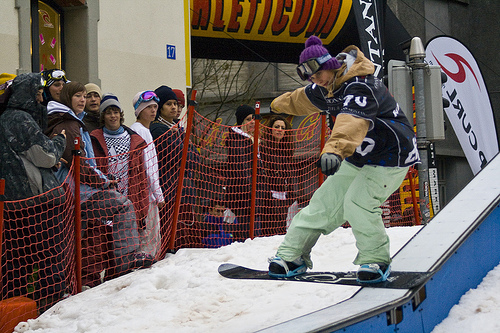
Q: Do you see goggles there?
A: Yes, there are goggles.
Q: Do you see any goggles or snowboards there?
A: Yes, there are goggles.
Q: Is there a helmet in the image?
A: No, there are no helmets.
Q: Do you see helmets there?
A: No, there are no helmets.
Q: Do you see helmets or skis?
A: No, there are no helmets or skis.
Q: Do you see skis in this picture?
A: No, there are no skis.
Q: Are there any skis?
A: No, there are no skis.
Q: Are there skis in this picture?
A: No, there are no skis.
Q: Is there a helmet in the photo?
A: No, there are no helmets.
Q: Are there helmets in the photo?
A: No, there are no helmets.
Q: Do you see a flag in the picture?
A: Yes, there is a flag.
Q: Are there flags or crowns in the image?
A: Yes, there is a flag.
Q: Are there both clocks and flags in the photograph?
A: No, there is a flag but no clocks.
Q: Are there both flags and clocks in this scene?
A: No, there is a flag but no clocks.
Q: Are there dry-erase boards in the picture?
A: No, there are no dry-erase boards.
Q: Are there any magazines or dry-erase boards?
A: No, there are no dry-erase boards or magazines.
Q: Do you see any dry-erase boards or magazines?
A: No, there are no dry-erase boards or magazines.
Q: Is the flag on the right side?
A: Yes, the flag is on the right of the image.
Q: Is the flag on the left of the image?
A: No, the flag is on the right of the image.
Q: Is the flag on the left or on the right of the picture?
A: The flag is on the right of the image.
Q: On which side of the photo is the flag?
A: The flag is on the right of the image.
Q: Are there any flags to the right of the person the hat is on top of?
A: Yes, there is a flag to the right of the person.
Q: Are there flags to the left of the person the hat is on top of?
A: No, the flag is to the right of the person.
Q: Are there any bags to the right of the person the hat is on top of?
A: No, there is a flag to the right of the person.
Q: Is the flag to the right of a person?
A: Yes, the flag is to the right of a person.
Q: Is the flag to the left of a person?
A: No, the flag is to the right of a person.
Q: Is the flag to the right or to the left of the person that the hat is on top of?
A: The flag is to the right of the person.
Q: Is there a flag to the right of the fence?
A: Yes, there is a flag to the right of the fence.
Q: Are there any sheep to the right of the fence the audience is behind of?
A: No, there is a flag to the right of the fence.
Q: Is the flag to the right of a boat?
A: No, the flag is to the right of the fence.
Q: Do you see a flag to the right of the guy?
A: Yes, there is a flag to the right of the guy.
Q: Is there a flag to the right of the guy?
A: Yes, there is a flag to the right of the guy.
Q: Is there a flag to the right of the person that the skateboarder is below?
A: Yes, there is a flag to the right of the guy.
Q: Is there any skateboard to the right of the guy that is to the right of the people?
A: No, there is a flag to the right of the guy.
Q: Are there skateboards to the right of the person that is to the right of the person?
A: No, there is a flag to the right of the guy.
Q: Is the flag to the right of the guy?
A: Yes, the flag is to the right of the guy.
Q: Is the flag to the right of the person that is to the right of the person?
A: Yes, the flag is to the right of the guy.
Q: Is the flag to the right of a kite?
A: No, the flag is to the right of the guy.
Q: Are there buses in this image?
A: No, there are no buses.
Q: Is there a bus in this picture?
A: No, there are no buses.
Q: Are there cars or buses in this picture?
A: No, there are no buses or cars.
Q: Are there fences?
A: Yes, there is a fence.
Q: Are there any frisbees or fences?
A: Yes, there is a fence.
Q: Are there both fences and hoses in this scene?
A: No, there is a fence but no hoses.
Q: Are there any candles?
A: No, there are no candles.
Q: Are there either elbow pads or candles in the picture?
A: No, there are no candles or elbow pads.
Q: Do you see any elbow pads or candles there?
A: No, there are no candles or elbow pads.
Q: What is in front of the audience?
A: The fence is in front of the audience.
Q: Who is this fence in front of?
A: The fence is in front of the audience.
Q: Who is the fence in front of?
A: The fence is in front of the audience.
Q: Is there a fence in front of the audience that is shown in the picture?
A: Yes, there is a fence in front of the audience.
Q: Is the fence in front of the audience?
A: Yes, the fence is in front of the audience.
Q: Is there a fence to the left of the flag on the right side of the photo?
A: Yes, there is a fence to the left of the flag.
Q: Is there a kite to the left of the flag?
A: No, there is a fence to the left of the flag.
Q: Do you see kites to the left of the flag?
A: No, there is a fence to the left of the flag.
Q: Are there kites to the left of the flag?
A: No, there is a fence to the left of the flag.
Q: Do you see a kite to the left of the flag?
A: No, there is a fence to the left of the flag.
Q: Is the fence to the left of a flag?
A: Yes, the fence is to the left of a flag.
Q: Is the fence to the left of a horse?
A: No, the fence is to the left of a flag.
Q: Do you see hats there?
A: Yes, there is a hat.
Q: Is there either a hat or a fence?
A: Yes, there is a hat.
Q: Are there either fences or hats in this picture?
A: Yes, there is a hat.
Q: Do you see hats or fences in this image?
A: Yes, there is a hat.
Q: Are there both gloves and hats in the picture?
A: Yes, there are both a hat and gloves.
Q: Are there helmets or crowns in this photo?
A: No, there are no helmets or crowns.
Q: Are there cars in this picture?
A: No, there are no cars.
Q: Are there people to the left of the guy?
A: Yes, there is a person to the left of the guy.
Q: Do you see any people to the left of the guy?
A: Yes, there is a person to the left of the guy.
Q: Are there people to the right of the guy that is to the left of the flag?
A: No, the person is to the left of the guy.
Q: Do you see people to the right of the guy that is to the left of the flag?
A: No, the person is to the left of the guy.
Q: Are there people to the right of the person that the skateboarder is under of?
A: No, the person is to the left of the guy.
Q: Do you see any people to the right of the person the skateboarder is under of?
A: No, the person is to the left of the guy.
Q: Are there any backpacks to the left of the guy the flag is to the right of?
A: No, there is a person to the left of the guy.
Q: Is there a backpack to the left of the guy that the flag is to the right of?
A: No, there is a person to the left of the guy.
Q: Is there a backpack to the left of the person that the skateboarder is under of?
A: No, there is a person to the left of the guy.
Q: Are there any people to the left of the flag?
A: Yes, there is a person to the left of the flag.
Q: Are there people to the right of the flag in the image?
A: No, the person is to the left of the flag.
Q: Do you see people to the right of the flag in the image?
A: No, the person is to the left of the flag.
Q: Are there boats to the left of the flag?
A: No, there is a person to the left of the flag.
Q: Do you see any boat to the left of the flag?
A: No, there is a person to the left of the flag.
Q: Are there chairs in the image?
A: No, there are no chairs.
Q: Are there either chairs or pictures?
A: No, there are no chairs or pictures.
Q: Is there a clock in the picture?
A: No, there are no clocks.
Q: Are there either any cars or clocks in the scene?
A: No, there are no clocks or cars.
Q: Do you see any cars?
A: No, there are no cars.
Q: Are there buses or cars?
A: No, there are no cars or buses.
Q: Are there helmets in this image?
A: No, there are no helmets.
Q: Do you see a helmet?
A: No, there are no helmets.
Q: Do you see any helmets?
A: No, there are no helmets.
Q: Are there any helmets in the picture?
A: No, there are no helmets.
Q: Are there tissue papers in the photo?
A: No, there are no tissue papers.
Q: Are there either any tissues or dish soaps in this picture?
A: No, there are no tissues or dish soaps.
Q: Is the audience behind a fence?
A: Yes, the audience is behind a fence.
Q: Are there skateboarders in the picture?
A: Yes, there is a skateboarder.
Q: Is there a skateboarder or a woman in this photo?
A: Yes, there is a skateboarder.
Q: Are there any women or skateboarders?
A: Yes, there is a skateboarder.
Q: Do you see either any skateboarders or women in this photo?
A: Yes, there is a skateboarder.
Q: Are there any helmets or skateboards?
A: No, there are no helmets or skateboards.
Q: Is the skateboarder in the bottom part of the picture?
A: Yes, the skateboarder is in the bottom of the image.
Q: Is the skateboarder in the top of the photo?
A: No, the skateboarder is in the bottom of the image.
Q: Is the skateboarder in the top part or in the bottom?
A: The skateboarder is in the bottom of the image.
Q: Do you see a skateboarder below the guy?
A: Yes, there is a skateboarder below the guy.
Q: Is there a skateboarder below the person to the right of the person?
A: Yes, there is a skateboarder below the guy.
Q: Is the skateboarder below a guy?
A: Yes, the skateboarder is below a guy.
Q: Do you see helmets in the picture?
A: No, there are no helmets.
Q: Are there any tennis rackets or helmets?
A: No, there are no helmets or tennis rackets.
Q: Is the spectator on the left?
A: Yes, the spectator is on the left of the image.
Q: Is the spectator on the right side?
A: No, the spectator is on the left of the image.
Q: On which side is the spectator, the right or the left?
A: The spectator is on the left of the image.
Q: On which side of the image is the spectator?
A: The spectator is on the left of the image.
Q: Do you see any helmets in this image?
A: No, there are no helmets.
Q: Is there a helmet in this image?
A: No, there are no helmets.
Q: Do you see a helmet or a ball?
A: No, there are no helmets or balls.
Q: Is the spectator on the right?
A: No, the spectator is on the left of the image.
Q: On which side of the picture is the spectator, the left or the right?
A: The spectator is on the left of the image.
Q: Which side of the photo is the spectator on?
A: The spectator is on the left of the image.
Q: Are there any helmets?
A: No, there are no helmets.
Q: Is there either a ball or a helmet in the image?
A: No, there are no helmets or balls.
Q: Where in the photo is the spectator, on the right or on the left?
A: The spectator is on the left of the image.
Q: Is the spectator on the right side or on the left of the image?
A: The spectator is on the left of the image.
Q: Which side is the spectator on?
A: The spectator is on the left of the image.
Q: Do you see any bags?
A: No, there are no bags.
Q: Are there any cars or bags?
A: No, there are no bags or cars.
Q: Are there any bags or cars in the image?
A: No, there are no bags or cars.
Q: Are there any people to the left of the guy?
A: Yes, there are people to the left of the guy.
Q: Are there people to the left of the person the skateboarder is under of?
A: Yes, there are people to the left of the guy.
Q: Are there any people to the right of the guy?
A: No, the people are to the left of the guy.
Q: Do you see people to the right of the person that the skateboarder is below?
A: No, the people are to the left of the guy.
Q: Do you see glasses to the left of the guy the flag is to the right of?
A: No, there are people to the left of the guy.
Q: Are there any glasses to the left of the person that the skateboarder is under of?
A: No, there are people to the left of the guy.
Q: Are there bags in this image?
A: No, there are no bags.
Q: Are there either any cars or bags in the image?
A: No, there are no bags or cars.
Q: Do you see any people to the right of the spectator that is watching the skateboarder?
A: Yes, there are people to the right of the spectator.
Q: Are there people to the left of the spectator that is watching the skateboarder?
A: No, the people are to the right of the spectator.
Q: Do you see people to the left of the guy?
A: Yes, there are people to the left of the guy.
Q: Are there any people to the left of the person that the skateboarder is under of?
A: Yes, there are people to the left of the guy.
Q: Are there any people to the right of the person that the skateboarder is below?
A: No, the people are to the left of the guy.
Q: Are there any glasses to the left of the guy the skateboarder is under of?
A: No, there are people to the left of the guy.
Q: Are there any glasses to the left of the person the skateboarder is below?
A: No, there are people to the left of the guy.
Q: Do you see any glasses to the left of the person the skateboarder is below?
A: No, there are people to the left of the guy.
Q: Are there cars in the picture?
A: No, there are no cars.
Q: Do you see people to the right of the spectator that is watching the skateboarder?
A: Yes, there are people to the right of the spectator.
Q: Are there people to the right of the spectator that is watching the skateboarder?
A: Yes, there are people to the right of the spectator.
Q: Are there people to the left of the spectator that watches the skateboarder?
A: No, the people are to the right of the spectator.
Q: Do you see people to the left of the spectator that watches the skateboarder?
A: No, the people are to the right of the spectator.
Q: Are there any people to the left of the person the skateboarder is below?
A: Yes, there are people to the left of the guy.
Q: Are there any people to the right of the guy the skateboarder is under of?
A: No, the people are to the left of the guy.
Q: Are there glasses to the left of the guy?
A: No, there are people to the left of the guy.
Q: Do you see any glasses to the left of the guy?
A: No, there are people to the left of the guy.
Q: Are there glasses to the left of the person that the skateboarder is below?
A: No, there are people to the left of the guy.